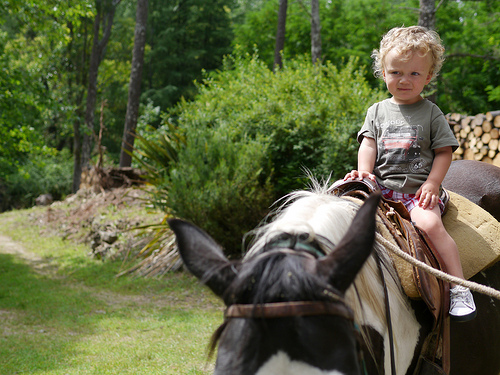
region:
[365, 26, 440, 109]
Small child with blonde curly hair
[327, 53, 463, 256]
Child riding horse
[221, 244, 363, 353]
Horse's brown harness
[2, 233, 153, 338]
Dirt path in woods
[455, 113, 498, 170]
Stack of chopped wood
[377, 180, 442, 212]
Child's red and white plaid shorts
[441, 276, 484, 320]
Child's white shoes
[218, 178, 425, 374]
Brown and white horse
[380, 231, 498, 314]
Beige rope attached to horse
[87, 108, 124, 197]
Dead tree stump in woods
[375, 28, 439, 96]
Boy has blonde hair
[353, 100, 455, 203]
boy has gray shirt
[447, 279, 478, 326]
child wearing white shoes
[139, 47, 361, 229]
bush growing behind the child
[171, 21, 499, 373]
child is riding a horse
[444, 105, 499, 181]
logs are stacked behind the child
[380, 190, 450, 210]
child is wearing red shorts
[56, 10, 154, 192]
tress growing in the background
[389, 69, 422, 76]
child has blue eyes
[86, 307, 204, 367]
grass is green in the sun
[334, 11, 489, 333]
a toddler on a horse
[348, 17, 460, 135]
toddler is blond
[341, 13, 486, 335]
toddler wears white shoes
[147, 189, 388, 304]
ears of horse are brown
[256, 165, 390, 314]
mane of horse is white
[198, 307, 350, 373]
face of horse is brown and white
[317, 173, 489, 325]
a brown saddle on a horse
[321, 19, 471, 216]
right hand of a toddler on saddle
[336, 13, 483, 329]
kid wears a squared short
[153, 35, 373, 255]
a green bush behind a horse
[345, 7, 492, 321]
Toddler sitting on top of horse.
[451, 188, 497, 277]
Edge of blanket under horse saddle.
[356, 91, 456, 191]
Toddler dressed in gray t-shirt.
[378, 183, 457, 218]
Toddler dressed in red and white plaid shorts.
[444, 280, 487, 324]
Toddler wearing white tennis shoe on foot.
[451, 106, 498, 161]
Stacked wood in background behind toddler and horse.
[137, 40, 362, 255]
Huge bush growing next to wood pile.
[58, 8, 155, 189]
Trunks of trees growing in woods.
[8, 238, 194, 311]
Path leading through grass.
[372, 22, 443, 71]
Blonde curly hair on toddler's head.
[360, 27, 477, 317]
Small boy sitting on horse.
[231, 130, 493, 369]
Black and white horse.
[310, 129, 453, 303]
Brown saddle on horse.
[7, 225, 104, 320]
Dirt path in the grass.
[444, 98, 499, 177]
Cut wood in the background.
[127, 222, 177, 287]
Pile of sticks on the ground.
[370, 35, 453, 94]
Blond curly hair on boy.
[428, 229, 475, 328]
White shoes on the boy.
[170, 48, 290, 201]
Large green bush behind horse.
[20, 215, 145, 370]
Shadow of tree top on ground.